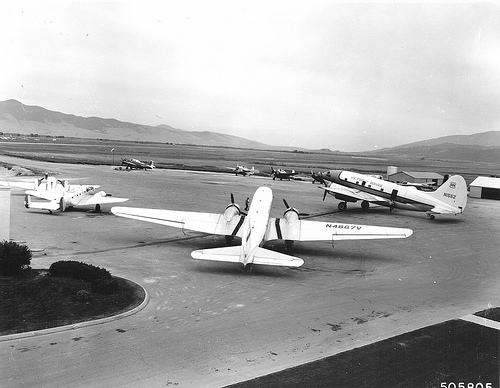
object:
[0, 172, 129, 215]
air plane's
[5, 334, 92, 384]
tarmac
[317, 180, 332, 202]
propellers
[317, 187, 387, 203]
wing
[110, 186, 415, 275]
air plane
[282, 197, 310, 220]
propellar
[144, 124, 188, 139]
mountains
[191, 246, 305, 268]
tail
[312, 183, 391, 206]
wing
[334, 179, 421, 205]
stripe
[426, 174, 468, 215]
tail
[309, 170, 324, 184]
airplanes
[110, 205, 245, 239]
wing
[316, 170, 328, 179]
nose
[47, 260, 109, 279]
bushes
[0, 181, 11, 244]
building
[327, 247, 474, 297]
tarmac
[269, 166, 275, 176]
nose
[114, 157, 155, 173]
airplane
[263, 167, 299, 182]
airplane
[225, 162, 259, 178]
airplane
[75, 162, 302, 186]
tarmac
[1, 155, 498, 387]
runway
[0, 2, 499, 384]
outdoors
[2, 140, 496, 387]
airport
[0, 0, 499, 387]
photo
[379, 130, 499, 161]
mountains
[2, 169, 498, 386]
paved area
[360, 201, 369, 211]
wheel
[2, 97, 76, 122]
mountain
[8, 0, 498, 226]
distance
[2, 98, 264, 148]
mountain range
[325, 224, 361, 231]
black writing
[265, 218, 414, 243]
plane wing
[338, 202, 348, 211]
wheel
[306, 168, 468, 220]
air plane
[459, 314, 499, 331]
line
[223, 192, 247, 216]
propeller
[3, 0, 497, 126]
bright sky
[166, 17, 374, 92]
clouds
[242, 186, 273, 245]
body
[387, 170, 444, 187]
structure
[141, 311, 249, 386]
tarmac